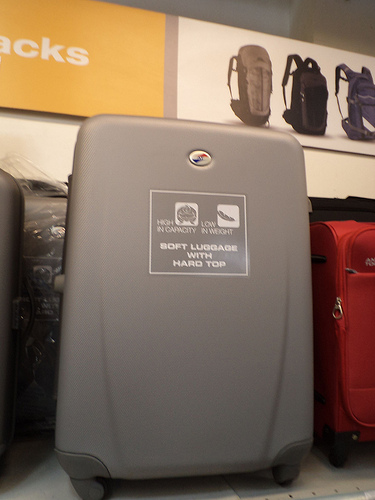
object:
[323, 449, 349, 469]
wheels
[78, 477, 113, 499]
wheels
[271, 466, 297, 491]
wheels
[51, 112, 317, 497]
luggage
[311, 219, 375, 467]
luggage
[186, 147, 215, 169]
logo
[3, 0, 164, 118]
sign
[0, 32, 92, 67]
letters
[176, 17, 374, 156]
picture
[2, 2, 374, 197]
wall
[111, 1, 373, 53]
ceiling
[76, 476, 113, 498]
wheel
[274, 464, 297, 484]
wheel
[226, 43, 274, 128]
illustrations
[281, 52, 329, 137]
illustrations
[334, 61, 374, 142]
illustrations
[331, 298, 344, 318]
zipper